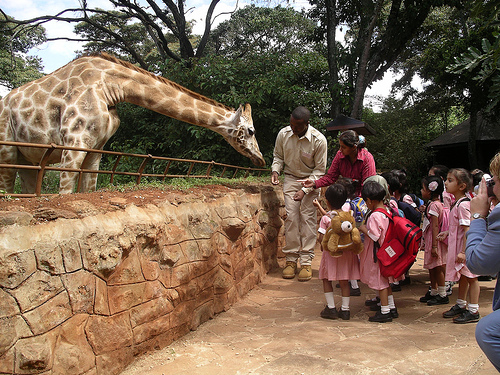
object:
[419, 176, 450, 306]
girl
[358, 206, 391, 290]
dress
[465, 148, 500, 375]
man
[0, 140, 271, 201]
fence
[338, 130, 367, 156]
head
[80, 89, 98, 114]
spot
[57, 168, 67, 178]
spot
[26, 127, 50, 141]
spot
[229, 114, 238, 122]
spot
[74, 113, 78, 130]
spot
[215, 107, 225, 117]
spot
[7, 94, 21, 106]
spot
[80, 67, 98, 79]
spot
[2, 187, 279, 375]
wall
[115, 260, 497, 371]
path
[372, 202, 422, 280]
backpack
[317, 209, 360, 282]
dress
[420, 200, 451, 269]
dress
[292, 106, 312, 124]
hair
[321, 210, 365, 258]
backpack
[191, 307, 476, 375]
ground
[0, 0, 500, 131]
tall trees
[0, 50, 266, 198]
brown/white giraffe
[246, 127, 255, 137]
black-giraffes eye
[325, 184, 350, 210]
black hair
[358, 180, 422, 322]
girl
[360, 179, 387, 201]
short hair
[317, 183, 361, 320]
girl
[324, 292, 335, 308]
white socks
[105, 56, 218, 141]
long neck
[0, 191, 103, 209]
brown fence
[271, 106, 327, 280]
black man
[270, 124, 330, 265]
khaki uniform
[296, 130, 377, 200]
black-haired woman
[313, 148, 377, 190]
pink shirt